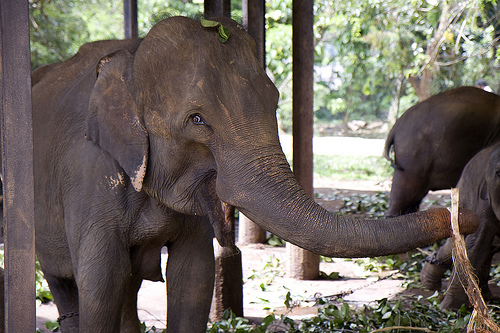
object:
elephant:
[31, 15, 477, 331]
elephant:
[381, 86, 499, 218]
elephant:
[417, 144, 499, 309]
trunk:
[211, 134, 481, 258]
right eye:
[188, 112, 210, 126]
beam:
[2, 1, 35, 332]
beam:
[288, 0, 319, 279]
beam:
[238, 0, 267, 242]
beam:
[203, 0, 243, 325]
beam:
[122, 0, 138, 41]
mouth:
[202, 169, 237, 248]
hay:
[449, 189, 499, 332]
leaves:
[353, 18, 365, 29]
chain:
[56, 309, 82, 325]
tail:
[381, 130, 404, 174]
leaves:
[220, 319, 238, 332]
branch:
[413, 0, 470, 97]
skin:
[129, 154, 149, 193]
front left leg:
[165, 223, 215, 331]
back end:
[393, 85, 500, 146]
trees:
[354, 0, 419, 129]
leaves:
[197, 17, 233, 43]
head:
[132, 15, 280, 246]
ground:
[0, 137, 499, 332]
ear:
[82, 52, 151, 194]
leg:
[63, 214, 135, 332]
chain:
[316, 248, 441, 306]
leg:
[417, 236, 454, 292]